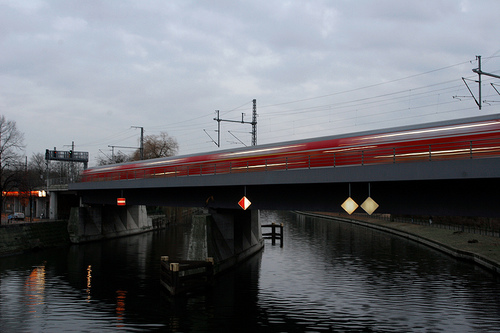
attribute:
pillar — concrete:
[150, 204, 262, 291]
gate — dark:
[260, 213, 285, 248]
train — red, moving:
[52, 96, 495, 213]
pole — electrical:
[450, 50, 499, 111]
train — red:
[65, 112, 497, 190]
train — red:
[80, 111, 498, 172]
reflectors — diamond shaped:
[335, 196, 381, 223]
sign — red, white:
[237, 194, 252, 210]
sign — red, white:
[114, 194, 127, 206]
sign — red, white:
[340, 196, 358, 216]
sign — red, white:
[359, 194, 381, 215]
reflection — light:
[74, 257, 99, 307]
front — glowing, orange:
[5, 164, 62, 214]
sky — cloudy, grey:
[66, 15, 323, 80]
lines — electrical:
[316, 90, 380, 112]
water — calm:
[19, 222, 481, 322]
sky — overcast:
[2, 5, 493, 170]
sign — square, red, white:
[234, 194, 256, 216]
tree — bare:
[3, 117, 30, 182]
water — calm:
[2, 220, 496, 330]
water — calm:
[258, 203, 493, 323]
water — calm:
[3, 251, 154, 328]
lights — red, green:
[47, 148, 84, 164]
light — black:
[48, 149, 80, 162]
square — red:
[115, 195, 126, 208]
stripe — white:
[117, 200, 126, 203]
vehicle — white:
[9, 210, 24, 220]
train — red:
[80, 110, 485, 183]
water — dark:
[12, 272, 482, 328]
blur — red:
[296, 132, 389, 167]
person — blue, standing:
[5, 214, 8, 221]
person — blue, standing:
[10, 213, 14, 221]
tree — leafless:
[0, 112, 25, 190]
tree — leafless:
[27, 151, 47, 185]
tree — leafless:
[50, 155, 80, 178]